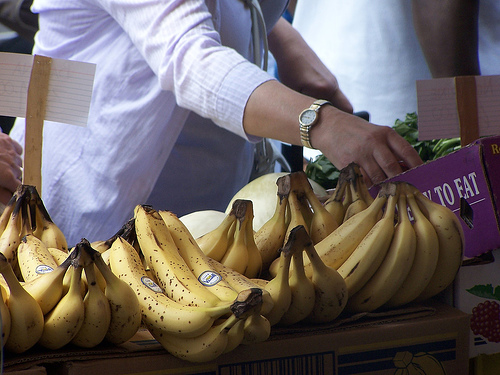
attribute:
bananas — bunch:
[270, 182, 462, 327]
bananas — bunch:
[325, 162, 372, 215]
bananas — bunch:
[105, 205, 273, 360]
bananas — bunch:
[12, 233, 142, 348]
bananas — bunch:
[69, 184, 485, 254]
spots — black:
[137, 259, 187, 309]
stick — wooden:
[15, 49, 51, 191]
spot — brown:
[147, 302, 153, 314]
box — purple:
[358, 140, 476, 231]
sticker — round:
[199, 267, 220, 287]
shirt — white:
[25, 0, 315, 287]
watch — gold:
[286, 89, 333, 136]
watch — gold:
[286, 93, 353, 158]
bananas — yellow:
[87, 208, 278, 359]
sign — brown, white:
[2, 48, 106, 132]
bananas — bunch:
[95, 200, 280, 367]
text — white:
[417, 163, 488, 207]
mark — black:
[147, 297, 157, 315]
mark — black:
[153, 305, 164, 329]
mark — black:
[183, 313, 201, 331]